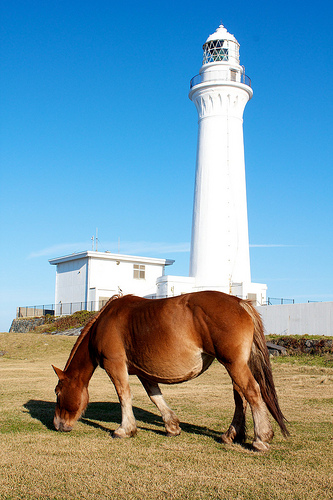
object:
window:
[140, 271, 145, 279]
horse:
[49, 288, 292, 452]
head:
[47, 361, 90, 433]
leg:
[98, 353, 136, 426]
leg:
[137, 372, 175, 420]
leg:
[225, 358, 274, 443]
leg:
[227, 384, 248, 428]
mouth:
[57, 420, 67, 434]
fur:
[97, 309, 130, 367]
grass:
[0, 330, 332, 499]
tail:
[240, 299, 293, 442]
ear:
[49, 362, 66, 381]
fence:
[18, 294, 332, 319]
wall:
[254, 300, 332, 337]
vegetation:
[273, 351, 332, 366]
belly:
[128, 336, 215, 385]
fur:
[133, 298, 197, 357]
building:
[46, 249, 176, 317]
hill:
[8, 308, 94, 334]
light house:
[186, 21, 253, 279]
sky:
[0, 0, 332, 336]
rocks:
[265, 342, 284, 359]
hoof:
[114, 423, 138, 442]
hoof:
[162, 414, 183, 436]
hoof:
[216, 424, 247, 448]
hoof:
[250, 421, 274, 454]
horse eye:
[54, 389, 61, 396]